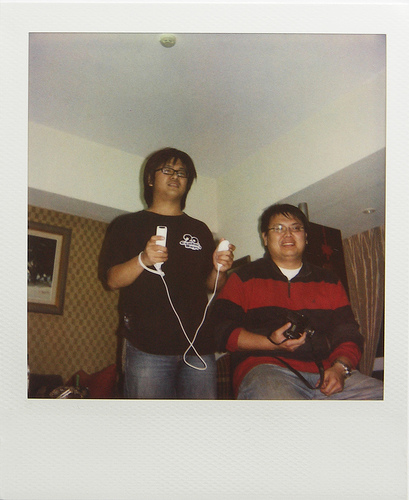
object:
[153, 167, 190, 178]
eyeglasses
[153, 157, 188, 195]
face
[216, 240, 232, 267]
game controllers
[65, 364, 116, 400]
pillow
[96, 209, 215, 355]
shirt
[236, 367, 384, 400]
jeans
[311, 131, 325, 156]
ground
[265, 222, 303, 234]
glasses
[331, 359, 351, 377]
watch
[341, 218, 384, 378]
curtains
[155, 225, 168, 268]
game controller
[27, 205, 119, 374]
wall paper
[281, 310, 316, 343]
camera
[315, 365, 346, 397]
hand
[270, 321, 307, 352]
hand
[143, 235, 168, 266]
hand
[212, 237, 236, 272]
hand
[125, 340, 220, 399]
jeans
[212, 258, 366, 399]
rugby shirt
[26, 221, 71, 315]
picture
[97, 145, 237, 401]
boy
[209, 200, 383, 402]
boy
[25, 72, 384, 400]
wall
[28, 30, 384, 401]
living room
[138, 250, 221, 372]
strap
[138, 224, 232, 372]
controller